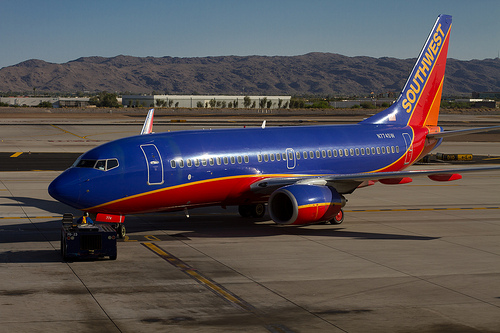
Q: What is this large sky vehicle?
A: Airplane.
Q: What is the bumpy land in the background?
A: Hills.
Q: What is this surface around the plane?
A: Concrete.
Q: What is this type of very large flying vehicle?
A: Airplane.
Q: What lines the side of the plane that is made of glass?
A: Windows.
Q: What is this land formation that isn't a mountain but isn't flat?
A: Hills.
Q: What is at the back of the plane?
A: A tail.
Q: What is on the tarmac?
A: A yellow line.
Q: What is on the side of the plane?
A: Windows.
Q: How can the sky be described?
A: Blue and clear.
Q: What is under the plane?
A: A shadow.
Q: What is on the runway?
A: Red and blue plane.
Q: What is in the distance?
A: Hills.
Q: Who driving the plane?
A: Pilot.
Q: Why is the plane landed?
A: It's refueling.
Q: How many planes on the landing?
A: One.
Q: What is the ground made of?
A: Cement.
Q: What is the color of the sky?
A: Blue.